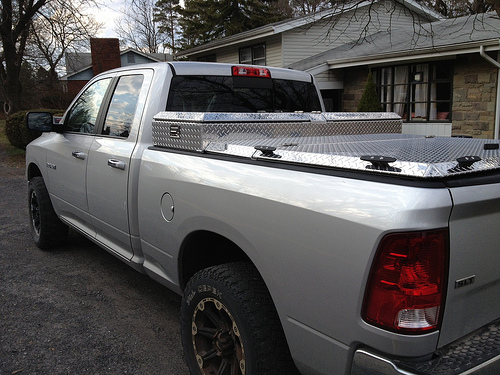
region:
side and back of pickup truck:
[22, 59, 489, 367]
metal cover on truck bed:
[233, 123, 490, 180]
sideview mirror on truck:
[18, 97, 72, 139]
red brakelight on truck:
[340, 218, 466, 340]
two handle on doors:
[67, 141, 136, 177]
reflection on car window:
[100, 71, 151, 136]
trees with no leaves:
[30, 3, 93, 48]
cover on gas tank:
[147, 180, 185, 231]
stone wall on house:
[456, 67, 491, 128]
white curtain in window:
[379, 65, 441, 112]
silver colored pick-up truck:
[104, 77, 344, 285]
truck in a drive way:
[110, 50, 483, 351]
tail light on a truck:
[337, 221, 465, 331]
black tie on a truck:
[186, 256, 272, 367]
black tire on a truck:
[17, 166, 72, 236]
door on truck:
[86, 65, 134, 222]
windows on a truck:
[56, 72, 137, 144]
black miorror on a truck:
[15, 95, 71, 141]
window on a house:
[373, 61, 453, 121]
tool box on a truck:
[155, 80, 395, 136]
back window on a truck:
[180, 72, 316, 110]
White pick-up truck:
[20, 30, 495, 337]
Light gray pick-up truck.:
[40, 32, 453, 362]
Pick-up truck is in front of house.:
[20, 25, 492, 345]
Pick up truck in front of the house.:
[26, 5, 492, 362]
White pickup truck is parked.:
[20, 35, 495, 360]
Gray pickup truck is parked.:
[25, 15, 495, 345]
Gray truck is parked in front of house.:
[17, 30, 492, 340]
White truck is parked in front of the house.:
[44, 38, 492, 343]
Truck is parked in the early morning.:
[31, 28, 496, 360]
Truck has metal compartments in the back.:
[14, 41, 496, 353]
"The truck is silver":
[9, 46, 496, 373]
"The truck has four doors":
[12, 57, 498, 366]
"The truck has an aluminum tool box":
[150, 88, 436, 150]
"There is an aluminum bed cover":
[158, 114, 498, 230]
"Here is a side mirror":
[16, 102, 71, 142]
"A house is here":
[169, 0, 497, 147]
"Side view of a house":
[42, 27, 198, 123]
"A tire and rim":
[171, 235, 335, 373]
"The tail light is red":
[348, 203, 494, 360]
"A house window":
[361, 49, 494, 154]